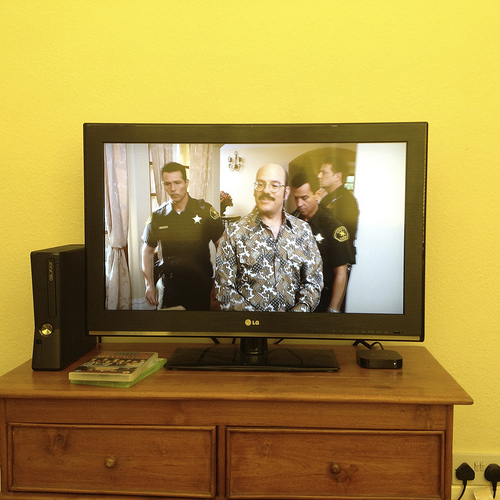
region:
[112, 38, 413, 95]
The wall is yellow.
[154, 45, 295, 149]
The wall is yellow.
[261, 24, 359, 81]
The wall is yellow.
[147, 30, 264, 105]
The wall is yellow.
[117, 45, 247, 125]
The wall is yellow.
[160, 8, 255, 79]
The wall is yellow.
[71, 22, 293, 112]
The wall is yellow.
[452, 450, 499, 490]
two black plugs in wall outlet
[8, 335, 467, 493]
brown wooden dresser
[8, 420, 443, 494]
two drawers in brown wooden dresser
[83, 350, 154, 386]
stack of magazines on top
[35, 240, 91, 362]
black xbox standing next to television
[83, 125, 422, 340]
black flat screen television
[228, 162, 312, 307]
man in floral shirt on television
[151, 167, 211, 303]
police officer on television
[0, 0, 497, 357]
TV in front of white wall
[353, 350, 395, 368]
internet router next to tv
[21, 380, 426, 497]
this is a cupboard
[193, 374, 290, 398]
the cupboard is brown in color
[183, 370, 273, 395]
the cupboard is wooden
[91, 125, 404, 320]
this is a television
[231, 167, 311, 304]
this is a man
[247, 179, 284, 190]
this is a spectacle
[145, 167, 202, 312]
this is a police officer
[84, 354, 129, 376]
this is a book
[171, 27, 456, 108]
this is the wall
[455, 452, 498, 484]
this is the socket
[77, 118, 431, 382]
black LG television on wood dresser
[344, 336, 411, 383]
black AppleTV on wood dresser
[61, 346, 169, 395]
green and white Xbox games on wood dresser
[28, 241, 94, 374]
black Xbox console on wood dresser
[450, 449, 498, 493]
white outlet on wall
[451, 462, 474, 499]
black cord plugged into white outlet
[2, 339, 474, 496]
brown wood dresser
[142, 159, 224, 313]
police officer on in the tv show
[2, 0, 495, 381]
yellow wall in the background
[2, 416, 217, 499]
brown dresser drawer in the wood dresser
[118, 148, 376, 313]
Four people on television screen.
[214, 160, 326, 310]
Man being arrested by police.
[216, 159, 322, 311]
Man wearing spectacles on his face.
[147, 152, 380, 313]
Three policemen in black uniform.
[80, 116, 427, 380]
Television on top of the table.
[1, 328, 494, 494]
Brown wooden cabinet with television sitting on it.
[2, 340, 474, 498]
Desk with two drawers.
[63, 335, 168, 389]
Books on top of the desk.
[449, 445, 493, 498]
A socket with two plugs on it.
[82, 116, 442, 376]
An LG television is on.